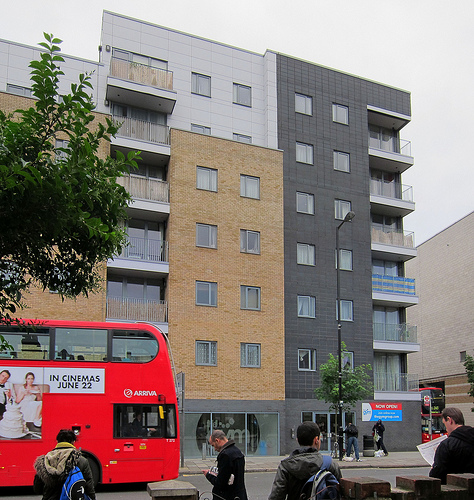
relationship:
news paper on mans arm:
[210, 465, 237, 488] [206, 459, 235, 488]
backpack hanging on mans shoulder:
[61, 467, 88, 499] [35, 428, 96, 499]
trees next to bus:
[1, 34, 137, 319] [1, 315, 181, 489]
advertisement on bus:
[2, 367, 107, 442] [1, 315, 181, 489]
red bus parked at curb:
[1, 315, 181, 489] [180, 464, 207, 478]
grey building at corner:
[277, 53, 424, 450] [279, 53, 474, 452]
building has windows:
[277, 53, 424, 450] [293, 89, 314, 118]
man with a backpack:
[35, 428, 96, 499] [61, 467, 88, 499]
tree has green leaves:
[1, 34, 137, 319] [36, 40, 50, 51]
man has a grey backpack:
[268, 421, 344, 499] [302, 456, 342, 500]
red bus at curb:
[1, 315, 181, 489] [180, 464, 207, 478]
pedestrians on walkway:
[346, 417, 391, 457] [338, 448, 421, 469]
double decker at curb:
[1, 315, 181, 489] [180, 464, 207, 478]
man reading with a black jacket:
[416, 408, 474, 476] [431, 427, 474, 471]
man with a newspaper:
[205, 429, 249, 500] [210, 465, 237, 488]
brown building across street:
[168, 127, 285, 400] [341, 464, 429, 482]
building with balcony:
[101, 11, 423, 451] [103, 55, 179, 115]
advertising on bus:
[2, 367, 107, 442] [1, 315, 181, 489]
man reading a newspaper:
[416, 408, 474, 476] [418, 433, 450, 465]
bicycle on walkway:
[329, 430, 357, 460] [338, 448, 421, 469]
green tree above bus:
[1, 34, 137, 319] [1, 315, 181, 489]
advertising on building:
[362, 401, 404, 424] [101, 11, 423, 451]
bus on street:
[1, 315, 181, 489] [341, 464, 429, 482]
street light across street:
[334, 211, 359, 459] [341, 464, 429, 482]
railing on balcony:
[368, 130, 413, 161] [367, 109, 413, 176]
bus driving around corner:
[412, 385, 447, 445] [401, 92, 458, 447]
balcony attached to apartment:
[103, 55, 179, 115] [367, 109, 413, 176]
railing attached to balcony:
[110, 54, 173, 73] [103, 55, 179, 115]